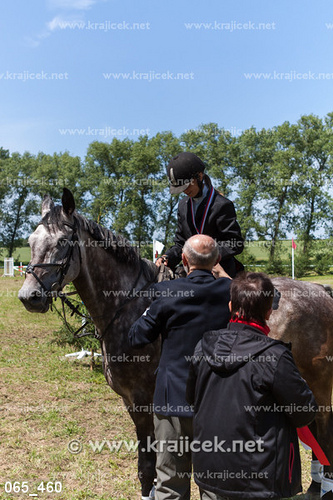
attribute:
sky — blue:
[1, 0, 332, 156]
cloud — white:
[19, 26, 51, 52]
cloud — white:
[47, 11, 81, 32]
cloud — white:
[41, 0, 98, 12]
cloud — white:
[2, 119, 50, 152]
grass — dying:
[0, 244, 332, 498]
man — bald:
[187, 236, 219, 269]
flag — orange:
[285, 229, 309, 276]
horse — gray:
[10, 207, 328, 481]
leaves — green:
[231, 126, 280, 233]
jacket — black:
[176, 281, 324, 493]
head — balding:
[176, 224, 224, 269]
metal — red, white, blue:
[185, 186, 216, 234]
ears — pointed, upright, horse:
[38, 187, 74, 219]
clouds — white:
[25, 2, 100, 49]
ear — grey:
[39, 191, 53, 216]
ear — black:
[59, 185, 73, 217]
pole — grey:
[285, 240, 296, 277]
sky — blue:
[277, 3, 325, 65]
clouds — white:
[40, 3, 82, 29]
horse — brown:
[24, 187, 332, 498]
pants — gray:
[155, 402, 213, 499]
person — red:
[188, 271, 315, 497]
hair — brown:
[227, 269, 276, 324]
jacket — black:
[189, 321, 310, 495]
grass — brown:
[303, 273, 330, 282]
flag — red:
[288, 238, 294, 251]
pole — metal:
[285, 242, 298, 281]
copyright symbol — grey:
[67, 438, 81, 453]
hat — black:
[167, 154, 206, 197]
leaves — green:
[275, 121, 295, 148]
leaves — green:
[269, 147, 297, 177]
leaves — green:
[256, 128, 277, 162]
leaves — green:
[264, 178, 285, 198]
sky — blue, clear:
[1, 0, 332, 238]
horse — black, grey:
[56, 206, 314, 383]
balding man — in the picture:
[128, 232, 237, 498]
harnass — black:
[31, 263, 66, 284]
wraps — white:
[308, 456, 331, 498]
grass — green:
[0, 377, 91, 487]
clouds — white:
[18, 10, 93, 59]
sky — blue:
[144, 32, 271, 108]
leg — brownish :
[302, 423, 329, 492]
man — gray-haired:
[130, 230, 240, 497]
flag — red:
[289, 237, 299, 249]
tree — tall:
[180, 118, 247, 233]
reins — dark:
[84, 254, 166, 338]